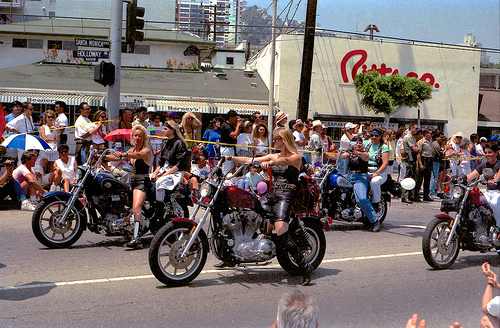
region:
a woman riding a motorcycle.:
[145, 121, 340, 286]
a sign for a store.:
[335, 48, 447, 104]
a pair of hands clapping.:
[450, 253, 498, 326]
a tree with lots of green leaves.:
[350, 67, 433, 124]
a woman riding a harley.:
[28, 110, 193, 256]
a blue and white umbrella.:
[0, 116, 65, 171]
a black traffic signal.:
[104, 0, 161, 57]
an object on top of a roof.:
[358, 21, 385, 48]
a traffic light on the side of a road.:
[121, 0, 155, 56]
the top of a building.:
[189, 0, 245, 49]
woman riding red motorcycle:
[193, 136, 330, 286]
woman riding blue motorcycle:
[76, 136, 183, 243]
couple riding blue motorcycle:
[328, 123, 408, 240]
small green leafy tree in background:
[363, 71, 425, 128]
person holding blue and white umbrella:
[21, 113, 68, 175]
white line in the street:
[343, 241, 438, 283]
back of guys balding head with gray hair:
[261, 278, 336, 325]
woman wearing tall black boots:
[283, 228, 330, 283]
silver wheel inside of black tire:
[151, 211, 226, 321]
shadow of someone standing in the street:
[8, 238, 48, 325]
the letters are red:
[336, 39, 457, 104]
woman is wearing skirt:
[256, 174, 296, 229]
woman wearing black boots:
[255, 216, 327, 281]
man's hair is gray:
[265, 279, 318, 326]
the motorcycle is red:
[426, 171, 492, 256]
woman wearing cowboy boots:
[119, 200, 154, 255]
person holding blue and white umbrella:
[0, 128, 82, 182]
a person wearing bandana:
[155, 114, 190, 141]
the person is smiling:
[479, 139, 497, 159]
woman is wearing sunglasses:
[263, 122, 290, 149]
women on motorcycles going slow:
[45, 113, 320, 280]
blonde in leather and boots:
[119, 122, 151, 257]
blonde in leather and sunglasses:
[257, 125, 341, 295]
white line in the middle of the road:
[58, 274, 125, 294]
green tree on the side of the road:
[349, 67, 447, 134]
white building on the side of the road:
[263, 25, 491, 135]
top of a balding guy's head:
[259, 283, 327, 325]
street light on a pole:
[116, 0, 156, 70]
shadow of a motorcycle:
[165, 267, 353, 297]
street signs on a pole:
[70, 32, 129, 68]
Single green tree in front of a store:
[352, 64, 435, 130]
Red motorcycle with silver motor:
[146, 178, 329, 288]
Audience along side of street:
[0, 95, 496, 215]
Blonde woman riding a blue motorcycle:
[122, 121, 156, 250]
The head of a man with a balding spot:
[266, 282, 328, 325]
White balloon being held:
[393, 172, 425, 195]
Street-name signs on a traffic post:
[68, 34, 114, 63]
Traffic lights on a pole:
[123, 0, 149, 54]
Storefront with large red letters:
[278, 33, 480, 145]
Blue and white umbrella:
[2, 128, 54, 156]